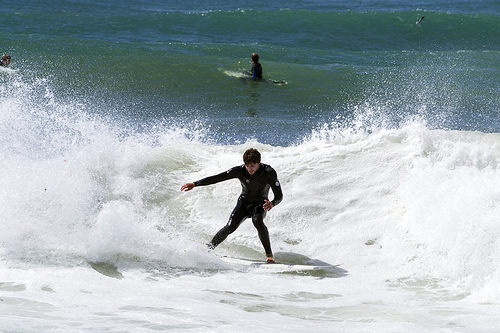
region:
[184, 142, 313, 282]
a man in a black wetsuit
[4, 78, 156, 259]
white ocean spray from the wave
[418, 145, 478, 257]
white ocean foam from the wave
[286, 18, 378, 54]
calm blue waters behind the wave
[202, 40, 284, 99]
a person sitting on a surfboard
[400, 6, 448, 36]
a person riding a wave in the distance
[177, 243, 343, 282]
a white surfboard in the water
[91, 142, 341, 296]
a man surfing on an ocean wave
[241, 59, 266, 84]
a person's blue and black wetsuit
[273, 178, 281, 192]
white patch on the man's arm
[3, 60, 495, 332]
the wave is crashing around the man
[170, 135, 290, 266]
the man is wet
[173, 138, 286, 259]
the man is in the ocean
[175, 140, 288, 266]
the man is surfing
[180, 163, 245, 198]
the man has his arm sticking out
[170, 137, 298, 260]
the man is wearing a wet suit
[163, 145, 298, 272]
the wet suit is black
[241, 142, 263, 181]
the man has short hair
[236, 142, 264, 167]
the man has dark hair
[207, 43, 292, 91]
the man is sitting on the surf board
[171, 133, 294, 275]
The man is surfing.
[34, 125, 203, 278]
This is a nice wave.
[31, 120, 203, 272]
The wave crest is white.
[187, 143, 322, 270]
The man has on a wetsuit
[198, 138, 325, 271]
The man's wetsuit is black.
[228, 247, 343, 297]
The surfboard is white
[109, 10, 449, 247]
This is in the ocean.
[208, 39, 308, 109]
this man is wading.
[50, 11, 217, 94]
The water here is blue.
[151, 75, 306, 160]
The water here is green.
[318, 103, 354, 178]
part of a splash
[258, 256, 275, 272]
part of a board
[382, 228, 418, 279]
part of a water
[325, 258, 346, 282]
part of a shade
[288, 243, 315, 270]
part of a shade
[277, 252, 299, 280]
part of a board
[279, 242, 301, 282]
dge of a board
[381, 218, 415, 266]
part of a splash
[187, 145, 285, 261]
a man surfing in the ocean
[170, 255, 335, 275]
a surfboard in the ocean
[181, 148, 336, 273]
a man on top of his surfboard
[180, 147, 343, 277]
a man riding a wave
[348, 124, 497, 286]
strong wave in the ocean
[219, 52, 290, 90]
a surfer waiting for a wave to ride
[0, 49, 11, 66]
a surfer's head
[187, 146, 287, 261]
a man wearing surfing gear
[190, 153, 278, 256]
a man wearing a black wetsuit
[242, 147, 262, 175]
a man with dark brown hair